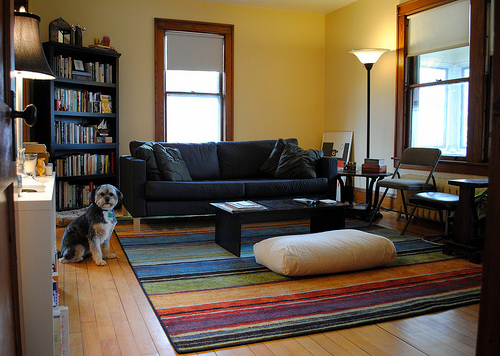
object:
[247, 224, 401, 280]
pillow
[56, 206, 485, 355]
floor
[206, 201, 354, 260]
center table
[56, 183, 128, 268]
dog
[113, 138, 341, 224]
couch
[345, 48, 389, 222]
floor lamp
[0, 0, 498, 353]
living room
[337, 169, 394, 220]
side table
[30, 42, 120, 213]
book shelf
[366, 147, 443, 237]
folding chair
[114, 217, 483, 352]
rug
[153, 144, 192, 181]
pillow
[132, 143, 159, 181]
pillow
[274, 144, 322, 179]
pillow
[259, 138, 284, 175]
pillow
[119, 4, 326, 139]
wall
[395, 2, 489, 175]
window